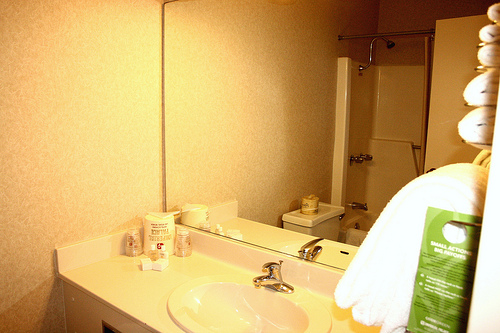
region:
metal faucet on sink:
[247, 250, 294, 295]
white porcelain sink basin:
[165, 266, 333, 331]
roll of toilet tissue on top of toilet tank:
[295, 193, 323, 217]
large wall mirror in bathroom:
[160, 3, 498, 265]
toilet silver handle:
[333, 212, 349, 224]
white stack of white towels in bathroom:
[454, 0, 499, 154]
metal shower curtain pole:
[336, 22, 436, 45]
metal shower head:
[351, 26, 401, 83]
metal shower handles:
[347, 140, 380, 169]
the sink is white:
[169, 270, 329, 331]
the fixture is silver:
[248, 261, 293, 293]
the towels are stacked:
[457, 2, 499, 142]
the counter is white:
[164, 269, 329, 329]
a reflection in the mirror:
[163, 3, 499, 270]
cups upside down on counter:
[125, 230, 187, 257]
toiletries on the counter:
[122, 210, 195, 268]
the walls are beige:
[1, 1, 163, 331]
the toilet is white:
[281, 200, 344, 242]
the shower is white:
[333, 61, 430, 226]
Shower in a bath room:
[338, 67, 430, 239]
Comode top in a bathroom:
[280, 181, 345, 234]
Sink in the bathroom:
[166, 257, 328, 331]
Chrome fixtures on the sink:
[251, 261, 296, 297]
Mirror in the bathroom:
[163, 4, 473, 267]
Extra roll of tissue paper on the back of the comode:
[297, 189, 323, 217]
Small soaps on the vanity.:
[135, 250, 172, 272]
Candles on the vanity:
[123, 225, 197, 259]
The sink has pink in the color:
[219, 283, 307, 330]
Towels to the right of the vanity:
[462, 8, 494, 148]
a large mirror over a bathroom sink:
[134, 33, 376, 309]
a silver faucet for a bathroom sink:
[245, 253, 300, 310]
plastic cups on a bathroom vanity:
[175, 222, 197, 269]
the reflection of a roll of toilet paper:
[279, 173, 351, 220]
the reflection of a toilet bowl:
[283, 177, 367, 244]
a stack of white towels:
[458, 13, 498, 173]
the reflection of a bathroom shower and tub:
[310, 28, 398, 235]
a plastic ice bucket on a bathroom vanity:
[141, 205, 176, 259]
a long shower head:
[357, 25, 397, 82]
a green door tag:
[403, 211, 478, 332]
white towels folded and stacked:
[459, 2, 499, 156]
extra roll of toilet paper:
[137, 212, 175, 257]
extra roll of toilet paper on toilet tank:
[272, 188, 346, 237]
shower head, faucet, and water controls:
[348, 29, 402, 221]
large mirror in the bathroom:
[158, 4, 426, 269]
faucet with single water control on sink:
[248, 256, 299, 296]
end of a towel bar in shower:
[408, 129, 430, 158]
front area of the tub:
[346, 210, 367, 250]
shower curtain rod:
[331, 23, 436, 51]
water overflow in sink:
[336, 242, 357, 262]